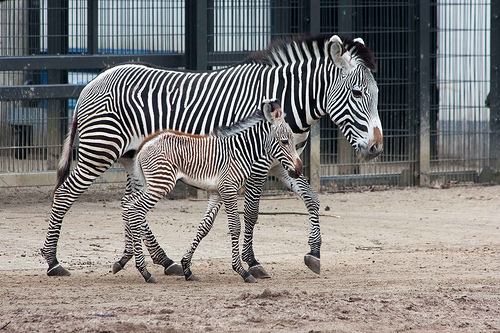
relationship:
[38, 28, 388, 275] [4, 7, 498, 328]
adult zebra walking in pen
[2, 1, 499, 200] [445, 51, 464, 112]
fence has wires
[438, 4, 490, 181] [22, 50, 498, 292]
fencing on an enclosure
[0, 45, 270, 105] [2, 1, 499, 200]
bars on a fence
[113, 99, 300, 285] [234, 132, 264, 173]
baby has stripes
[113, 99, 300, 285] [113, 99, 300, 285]
baby has baby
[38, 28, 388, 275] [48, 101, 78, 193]
adult zebra has tail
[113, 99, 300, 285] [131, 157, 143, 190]
baby has tail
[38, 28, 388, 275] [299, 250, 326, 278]
adult zebra has hoof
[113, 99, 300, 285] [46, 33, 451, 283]
baby walking with zebra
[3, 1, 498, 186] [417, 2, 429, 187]
cage has thin posts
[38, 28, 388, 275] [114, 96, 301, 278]
adult zebra and its baby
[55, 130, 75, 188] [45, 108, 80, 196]
fur at end of tail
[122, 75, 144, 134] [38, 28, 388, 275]
stripes on adult zebra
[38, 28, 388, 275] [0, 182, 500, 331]
adult zebra walking on dirt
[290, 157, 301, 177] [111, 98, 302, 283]
nose on zebra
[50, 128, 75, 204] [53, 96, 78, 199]
hair on zebra tail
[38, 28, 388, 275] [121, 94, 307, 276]
adult zebra with a baby zebra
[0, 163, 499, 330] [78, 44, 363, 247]
floor beneath zebra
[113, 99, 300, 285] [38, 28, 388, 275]
baby walking near adult zebra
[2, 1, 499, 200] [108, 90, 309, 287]
fence enclosing zebra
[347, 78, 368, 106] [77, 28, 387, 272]
eye of adult zebra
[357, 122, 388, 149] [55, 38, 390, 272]
nose of zebra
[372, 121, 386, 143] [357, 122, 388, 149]
marking on nose